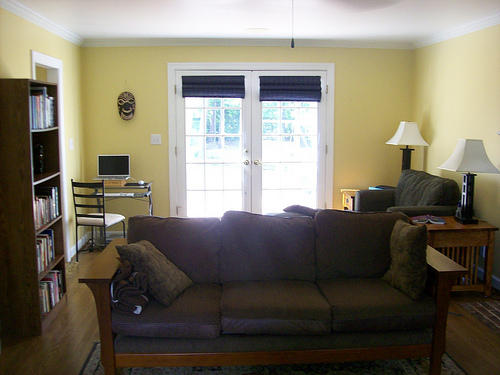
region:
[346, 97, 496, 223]
two white lamps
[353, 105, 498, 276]
two white lamps on brown tables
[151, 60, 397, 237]
white door frame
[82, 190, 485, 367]
a brown couch with brown pillows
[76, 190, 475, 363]
a brown couch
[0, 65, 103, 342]
a brown bookcase with books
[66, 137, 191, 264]
a silver computer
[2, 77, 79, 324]
a brown bookcase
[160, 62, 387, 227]
black shades on a door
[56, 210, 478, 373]
a rug underneath the couch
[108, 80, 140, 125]
mask hanging on the yellow wall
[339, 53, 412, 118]
yellow wall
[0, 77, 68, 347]
bookcase filled with books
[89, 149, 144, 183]
laptop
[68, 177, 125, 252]
dark colored chair with light colored cushion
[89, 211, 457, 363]
brown couch with wooden arm rests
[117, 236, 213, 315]
pillow and blanket on the couch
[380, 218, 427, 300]
pillow on the couch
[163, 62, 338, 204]
white double doots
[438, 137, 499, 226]
White shade lamp on wooden table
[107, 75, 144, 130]
decorative mask hanging on wall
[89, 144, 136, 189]
computer monitor sitting on desk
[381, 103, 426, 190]
black lamp with white shade sitting on table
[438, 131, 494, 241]
black lamp with white shade sitting on table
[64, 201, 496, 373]
wood and leather couch in middle of floor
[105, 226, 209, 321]
brown throw pillow on couch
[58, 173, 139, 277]
straight back chair with white cushion seat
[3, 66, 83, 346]
brown wooden bookcase with books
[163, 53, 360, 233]
french doors leading outside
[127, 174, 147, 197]
wired computer mouse sitting on table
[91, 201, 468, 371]
futon sofa with wood frame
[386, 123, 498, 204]
two white and black side lamps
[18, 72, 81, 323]
bookshelf with many books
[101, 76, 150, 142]
mask as decoration on wall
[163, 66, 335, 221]
light coming in through french doors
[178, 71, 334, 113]
black shades on french doors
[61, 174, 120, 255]
black and white chair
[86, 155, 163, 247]
computer screen on computer desk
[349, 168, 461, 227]
fluffy grey couch against the wall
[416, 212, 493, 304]
wood side table with book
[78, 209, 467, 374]
the sofa is grey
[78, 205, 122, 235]
the chair has a white seat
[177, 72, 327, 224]
the sun is shining through the door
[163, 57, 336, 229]
the door is white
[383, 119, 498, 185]
the lamps have white shades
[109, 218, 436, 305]
the sofa has two throw pillows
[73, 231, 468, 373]
the sofa has a wooden frame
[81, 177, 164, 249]
the computer is on a desk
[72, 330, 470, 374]
the sofa has a rug beneath it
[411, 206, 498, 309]
the end table is wood